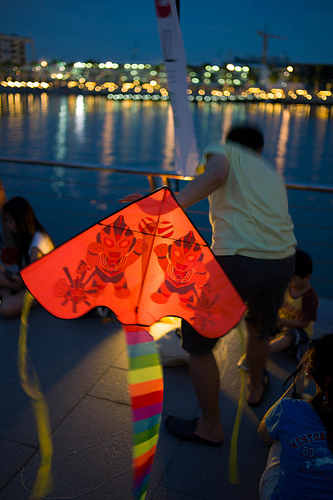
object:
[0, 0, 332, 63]
sky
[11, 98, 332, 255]
water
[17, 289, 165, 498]
lines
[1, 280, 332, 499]
ground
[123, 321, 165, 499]
tail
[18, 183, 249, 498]
kite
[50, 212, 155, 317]
figures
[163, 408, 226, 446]
shoe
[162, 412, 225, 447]
foot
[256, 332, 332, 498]
person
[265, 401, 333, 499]
shirt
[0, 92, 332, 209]
reflection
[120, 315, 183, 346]
light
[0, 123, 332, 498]
people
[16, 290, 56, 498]
tail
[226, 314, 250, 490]
tail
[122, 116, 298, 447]
person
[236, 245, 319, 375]
boy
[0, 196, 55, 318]
girl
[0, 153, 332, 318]
fence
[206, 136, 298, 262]
shirt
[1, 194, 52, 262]
hair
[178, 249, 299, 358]
shorts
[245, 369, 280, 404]
sandals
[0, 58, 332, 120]
lights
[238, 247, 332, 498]
kids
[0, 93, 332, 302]
shore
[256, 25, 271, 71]
crane